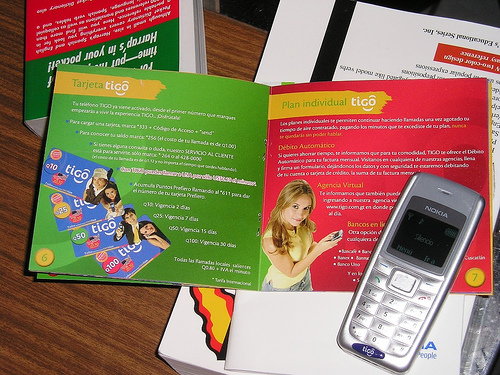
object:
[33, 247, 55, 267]
pages 6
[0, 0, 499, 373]
table top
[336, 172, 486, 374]
cellphone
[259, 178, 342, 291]
lady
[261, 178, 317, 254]
hair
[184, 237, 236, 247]
writing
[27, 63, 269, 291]
paper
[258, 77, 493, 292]
paper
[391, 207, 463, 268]
screen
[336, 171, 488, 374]
phone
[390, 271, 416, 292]
buttons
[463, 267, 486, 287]
page seven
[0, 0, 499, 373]
desk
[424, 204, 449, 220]
nokia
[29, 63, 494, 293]
book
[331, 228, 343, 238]
phone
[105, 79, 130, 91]
tigo